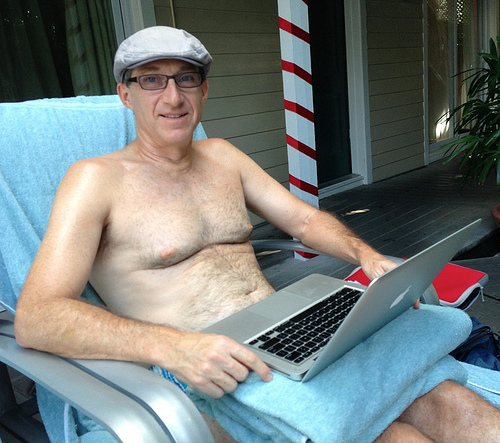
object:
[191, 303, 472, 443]
blanket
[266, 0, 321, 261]
beam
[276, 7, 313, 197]
stripes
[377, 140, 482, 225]
porch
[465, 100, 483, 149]
leaves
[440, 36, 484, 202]
plant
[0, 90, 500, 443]
chairs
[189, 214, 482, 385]
computer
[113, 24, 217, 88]
cap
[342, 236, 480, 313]
case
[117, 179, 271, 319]
chest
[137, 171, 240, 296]
hair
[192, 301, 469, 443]
lap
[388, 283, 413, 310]
logo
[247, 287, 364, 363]
keyboard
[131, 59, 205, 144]
face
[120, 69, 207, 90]
glasses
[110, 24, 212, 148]
head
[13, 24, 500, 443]
man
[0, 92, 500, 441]
towel